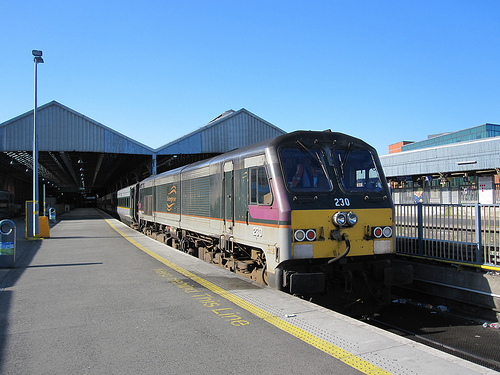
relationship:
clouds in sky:
[0, 0, 499, 149] [165, 17, 401, 83]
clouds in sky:
[0, 0, 499, 149] [66, 17, 440, 124]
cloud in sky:
[121, 112, 170, 132] [153, 15, 368, 72]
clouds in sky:
[0, 0, 499, 149] [107, 13, 470, 90]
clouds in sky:
[0, 0, 499, 149] [1, 2, 469, 112]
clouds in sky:
[0, 0, 499, 149] [76, 17, 486, 134]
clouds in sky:
[42, 5, 479, 86] [0, 1, 498, 156]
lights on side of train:
[372, 225, 392, 237] [91, 125, 402, 303]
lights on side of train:
[292, 228, 317, 241] [91, 125, 402, 303]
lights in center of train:
[321, 207, 369, 233] [72, 125, 409, 295]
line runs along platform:
[96, 209, 383, 374] [67, 206, 185, 367]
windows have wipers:
[276, 134, 388, 198] [283, 138, 380, 193]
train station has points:
[10, 110, 269, 160] [37, 84, 259, 120]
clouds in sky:
[0, 0, 499, 149] [2, 6, 497, 130]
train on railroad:
[160, 155, 405, 268] [319, 275, 481, 345]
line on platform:
[101, 214, 383, 374] [126, 226, 320, 374]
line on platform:
[96, 209, 383, 374] [5, 195, 498, 374]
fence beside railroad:
[394, 200, 499, 271] [319, 275, 500, 372]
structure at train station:
[378, 128, 496, 242] [5, 91, 495, 373]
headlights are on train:
[289, 225, 323, 245] [89, 117, 414, 296]